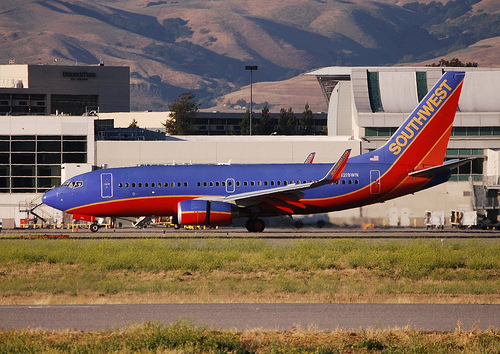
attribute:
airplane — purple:
[50, 64, 486, 234]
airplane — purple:
[33, 78, 474, 239]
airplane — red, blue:
[15, 69, 425, 253]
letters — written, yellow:
[362, 77, 477, 168]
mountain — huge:
[83, 8, 360, 134]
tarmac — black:
[58, 216, 436, 277]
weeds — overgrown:
[72, 220, 427, 290]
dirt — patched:
[71, 240, 354, 298]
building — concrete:
[3, 110, 115, 208]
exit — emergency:
[348, 161, 387, 192]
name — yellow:
[378, 81, 495, 198]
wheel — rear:
[245, 189, 285, 254]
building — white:
[41, 44, 471, 228]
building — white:
[33, 52, 473, 304]